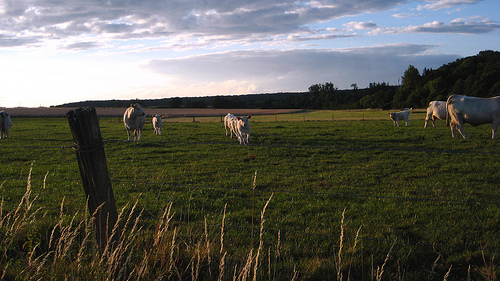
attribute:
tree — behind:
[305, 80, 342, 108]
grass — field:
[5, 112, 498, 279]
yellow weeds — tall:
[21, 200, 442, 280]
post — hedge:
[67, 100, 128, 237]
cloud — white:
[343, 17, 378, 34]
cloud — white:
[397, 13, 499, 35]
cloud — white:
[0, 1, 403, 52]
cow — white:
[118, 88, 211, 196]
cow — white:
[113, 90, 147, 156]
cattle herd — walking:
[118, 91, 498, 145]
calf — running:
[224, 111, 254, 148]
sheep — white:
[119, 98, 147, 139]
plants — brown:
[11, 155, 498, 279]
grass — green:
[289, 130, 414, 215]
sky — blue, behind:
[358, 39, 480, 47]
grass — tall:
[13, 170, 481, 275]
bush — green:
[426, 63, 488, 95]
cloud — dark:
[373, 19, 495, 37]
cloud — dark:
[0, 2, 399, 39]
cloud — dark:
[142, 42, 459, 86]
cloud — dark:
[415, 1, 477, 13]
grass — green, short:
[288, 153, 359, 238]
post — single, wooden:
[28, 85, 125, 251]